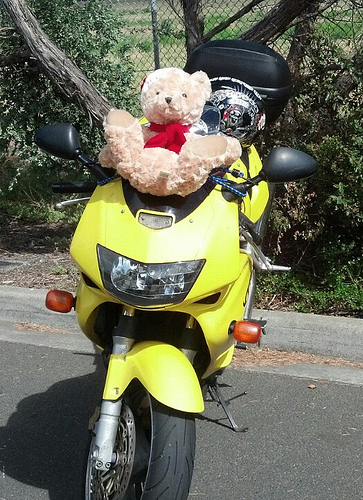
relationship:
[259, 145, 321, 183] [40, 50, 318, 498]
right mirror on motorcycle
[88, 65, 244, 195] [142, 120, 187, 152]
teddy bear has scarf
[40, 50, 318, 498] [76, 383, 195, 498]
motorcycle has wheel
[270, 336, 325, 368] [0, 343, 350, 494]
leaves on ground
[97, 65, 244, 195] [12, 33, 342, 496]
teddy bear on bike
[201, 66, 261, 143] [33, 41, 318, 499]
helmet on motorcycle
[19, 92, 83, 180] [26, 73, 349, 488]
mirror in motorcycle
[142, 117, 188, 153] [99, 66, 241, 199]
scarf on bear